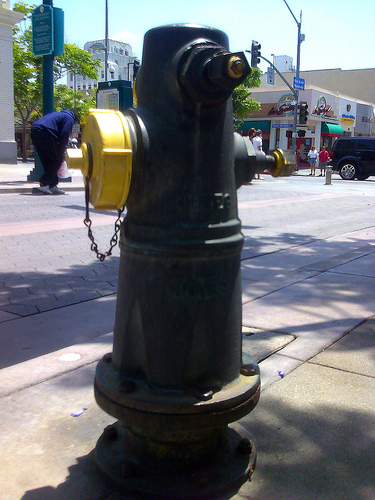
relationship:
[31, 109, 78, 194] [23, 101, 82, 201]
man wears pants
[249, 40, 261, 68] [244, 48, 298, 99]
traffic light on arm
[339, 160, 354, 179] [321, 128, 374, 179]
rear wheel on vehicle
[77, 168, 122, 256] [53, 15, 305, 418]
chain on hydrant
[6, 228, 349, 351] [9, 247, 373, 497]
shadows on sidewalk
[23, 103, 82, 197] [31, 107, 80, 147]
man wears sweatshirt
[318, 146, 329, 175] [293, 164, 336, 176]
person on sidewalk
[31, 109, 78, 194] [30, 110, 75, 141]
man wears shirt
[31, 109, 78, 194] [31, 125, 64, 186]
man wears pants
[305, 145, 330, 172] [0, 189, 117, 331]
people across street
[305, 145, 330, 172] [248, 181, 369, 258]
people across street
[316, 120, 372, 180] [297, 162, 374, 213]
automobile on street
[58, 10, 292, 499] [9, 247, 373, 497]
fire hydrant on sidewalk